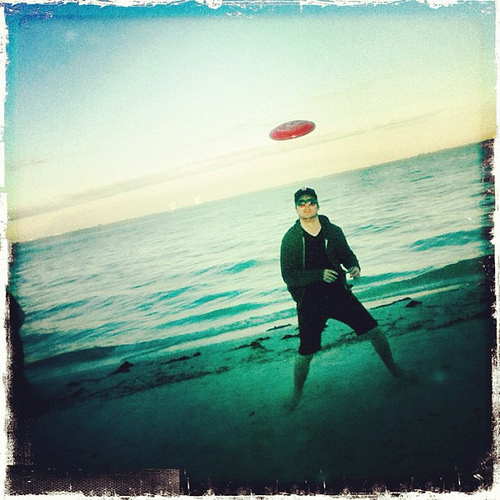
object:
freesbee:
[269, 118, 317, 140]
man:
[280, 187, 406, 412]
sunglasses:
[296, 199, 319, 208]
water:
[6, 137, 495, 375]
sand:
[9, 279, 495, 496]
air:
[190, 94, 239, 120]